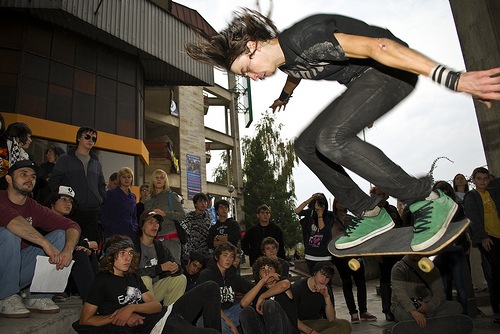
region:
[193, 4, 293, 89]
head of a person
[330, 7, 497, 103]
arm of a person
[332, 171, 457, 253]
a pair of green sneakers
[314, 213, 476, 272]
skateboard in mid air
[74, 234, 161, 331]
person wearing a hat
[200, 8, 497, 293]
person riding on skate board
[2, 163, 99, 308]
person wearing red shirt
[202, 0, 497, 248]
person wearing black shirt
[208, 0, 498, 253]
person in mid air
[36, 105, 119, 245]
person wearing sun glasses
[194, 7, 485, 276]
man riding skate board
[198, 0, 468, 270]
man on top of skateboard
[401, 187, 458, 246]
green shoes on feet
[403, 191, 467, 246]
green and white shoes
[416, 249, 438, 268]
yellow wheels on board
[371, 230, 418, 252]
black grip tape on board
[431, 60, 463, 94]
bracelets on wrist of man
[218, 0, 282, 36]
long hair of man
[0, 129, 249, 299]
group of people watching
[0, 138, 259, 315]
spectators watching boarder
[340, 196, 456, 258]
Green gym shoes on skateboard.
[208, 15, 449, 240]
The skater is wearing green shoes.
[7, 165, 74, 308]
Man holding white piece of paper.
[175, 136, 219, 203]
Poster attached to wall.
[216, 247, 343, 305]
Three boys watching skater.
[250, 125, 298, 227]
Green tree in the background.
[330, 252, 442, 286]
The skateboard has yellow wheels.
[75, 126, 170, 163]
Orange trim of building.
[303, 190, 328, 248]
Girl taking picture of skater.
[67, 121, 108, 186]
Boy in glasses in the crowd.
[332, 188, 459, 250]
green tennis shoes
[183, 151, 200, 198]
blue and purple poster on the wall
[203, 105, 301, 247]
trees with green leaves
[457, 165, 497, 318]
kid in a yellow shirt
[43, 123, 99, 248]
person wearing sunglasses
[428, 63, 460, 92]
white and black wrist bands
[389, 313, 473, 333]
black skateboard on the ground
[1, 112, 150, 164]
yellow bar on the building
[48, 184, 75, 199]
black and white trucker hat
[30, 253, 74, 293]
white paper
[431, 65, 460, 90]
white and black bracelets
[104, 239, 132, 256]
a blue head band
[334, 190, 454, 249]
green skate shoes with black laces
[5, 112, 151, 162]
orange accent on the building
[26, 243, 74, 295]
man is holding a piece of paper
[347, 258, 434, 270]
yellow wheels on the skateboard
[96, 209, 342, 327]
a group of boys sitting on the ground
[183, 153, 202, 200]
advertisement on the wall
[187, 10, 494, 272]
skateboarder is in the air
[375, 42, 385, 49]
scab on his elbow